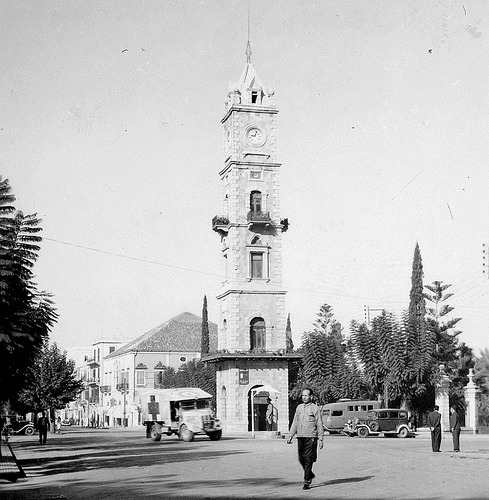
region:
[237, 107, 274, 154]
clock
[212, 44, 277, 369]
clock tower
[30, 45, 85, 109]
white clouds in blue sky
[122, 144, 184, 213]
white clouds in blue sky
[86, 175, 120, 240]
white clouds in blue sky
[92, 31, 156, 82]
white clouds in blue sky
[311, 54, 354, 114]
white clouds in blue sky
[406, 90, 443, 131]
white clouds in blue sky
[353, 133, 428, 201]
white clouds in blue sky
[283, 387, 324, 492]
person walking towards camera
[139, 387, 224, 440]
medical truck by building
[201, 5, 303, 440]
several stories clock tower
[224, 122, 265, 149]
two analog clocks can be seen on tower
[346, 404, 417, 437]
ford model T beside building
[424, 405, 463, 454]
two men in suits talking in street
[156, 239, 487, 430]
trees are behind clock tower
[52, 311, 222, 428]
buildings in row behind clock tower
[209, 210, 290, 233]
potted plants up high on tower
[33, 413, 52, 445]
person walking under tree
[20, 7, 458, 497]
a black and white photo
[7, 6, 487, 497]
a scene outside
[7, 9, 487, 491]
a photo during the day time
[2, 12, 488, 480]
a scene downtown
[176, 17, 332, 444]
a clock tower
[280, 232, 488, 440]
a cluster of trees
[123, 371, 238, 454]
an ambulance truck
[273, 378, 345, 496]
a person crossing the street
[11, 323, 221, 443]
a couple of buildings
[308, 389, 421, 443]
a couple of vehicles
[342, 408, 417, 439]
old car on the road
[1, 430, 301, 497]
shadows of trees on the ground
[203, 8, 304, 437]
tall brick clock tower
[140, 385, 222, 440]
truck driving on the road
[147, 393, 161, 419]
cross on the side of a truck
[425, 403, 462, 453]
two men in suits standing on the road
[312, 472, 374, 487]
shadow of a man on the road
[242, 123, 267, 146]
round clock at the top of a tower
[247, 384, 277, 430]
arched doorway with a guard standing to the side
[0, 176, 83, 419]
trees along the side of the road